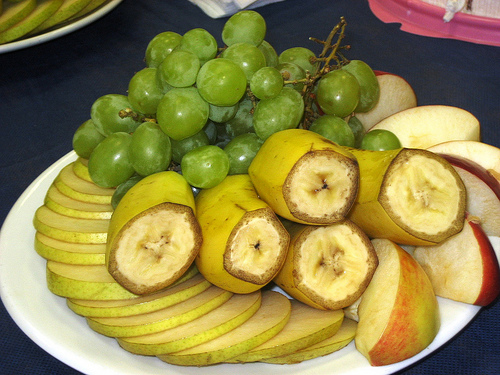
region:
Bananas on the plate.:
[116, 163, 446, 298]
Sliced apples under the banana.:
[371, 230, 458, 320]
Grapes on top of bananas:
[81, 82, 353, 141]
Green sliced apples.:
[53, 188, 115, 317]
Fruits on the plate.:
[33, 84, 380, 373]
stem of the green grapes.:
[308, 9, 353, 101]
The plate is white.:
[9, 207, 74, 329]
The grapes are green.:
[141, 55, 353, 139]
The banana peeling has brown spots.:
[221, 181, 253, 219]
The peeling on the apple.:
[379, 246, 429, 323]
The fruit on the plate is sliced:
[48, 175, 106, 311]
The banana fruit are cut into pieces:
[86, 131, 475, 309]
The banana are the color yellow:
[106, 174, 418, 283]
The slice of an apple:
[360, 237, 436, 363]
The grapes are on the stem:
[68, 30, 380, 151]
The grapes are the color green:
[82, 10, 382, 156]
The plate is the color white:
[0, 152, 498, 372]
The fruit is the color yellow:
[38, 202, 108, 318]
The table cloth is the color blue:
[323, 10, 498, 100]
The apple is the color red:
[439, 123, 499, 213]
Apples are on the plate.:
[352, 65, 493, 355]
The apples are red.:
[345, 62, 498, 352]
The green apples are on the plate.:
[37, 144, 357, 372]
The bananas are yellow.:
[104, 131, 468, 298]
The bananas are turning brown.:
[102, 135, 447, 320]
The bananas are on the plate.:
[109, 134, 478, 315]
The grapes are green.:
[55, 20, 400, 178]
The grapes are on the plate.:
[53, 10, 405, 178]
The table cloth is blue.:
[7, 11, 497, 348]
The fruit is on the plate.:
[5, 75, 499, 370]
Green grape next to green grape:
[129, 120, 170, 174]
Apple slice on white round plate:
[359, 237, 440, 367]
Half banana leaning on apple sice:
[286, 215, 374, 310]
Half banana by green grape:
[105, 174, 197, 298]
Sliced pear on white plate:
[157, 288, 291, 366]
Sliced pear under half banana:
[43, 261, 197, 304]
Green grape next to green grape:
[250, 65, 281, 99]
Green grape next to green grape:
[317, 68, 357, 115]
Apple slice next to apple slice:
[399, 208, 499, 305]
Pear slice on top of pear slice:
[217, 305, 349, 362]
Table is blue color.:
[5, 45, 75, 140]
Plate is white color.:
[12, 126, 482, 368]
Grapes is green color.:
[115, 36, 280, 131]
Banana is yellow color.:
[101, 126, 451, 268]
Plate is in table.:
[23, 75, 153, 190]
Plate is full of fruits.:
[52, 79, 474, 346]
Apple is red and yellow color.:
[357, 83, 491, 338]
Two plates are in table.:
[5, 14, 152, 193]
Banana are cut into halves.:
[102, 113, 464, 285]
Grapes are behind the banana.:
[116, 49, 344, 214]